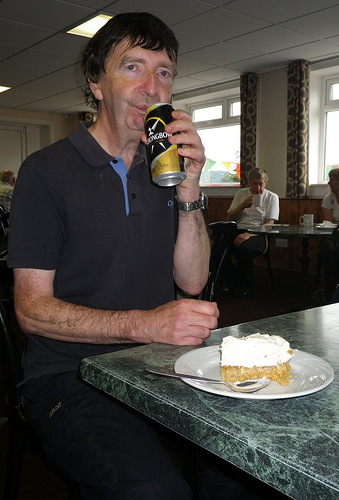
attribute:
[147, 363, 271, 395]
spoon — silver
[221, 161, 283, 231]
man — old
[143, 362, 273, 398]
spoon — large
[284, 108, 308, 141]
pattern — circular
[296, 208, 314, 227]
mug — white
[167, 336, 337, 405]
plate — round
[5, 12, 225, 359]
man — drinking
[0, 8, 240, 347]
an old man — eating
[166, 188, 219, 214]
metal wrist watch — silver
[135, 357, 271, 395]
spoon on a plate — silver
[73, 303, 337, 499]
marble painted table — green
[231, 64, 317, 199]
brown curtains — hanging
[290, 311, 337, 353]
marble top table — green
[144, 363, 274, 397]
sliver spoon — silver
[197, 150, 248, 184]
colored flags — stringer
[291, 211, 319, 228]
cup on a table — white, coffee